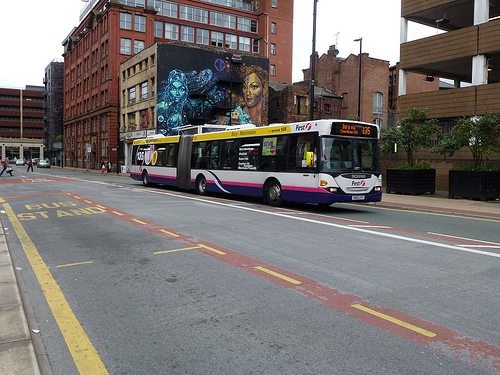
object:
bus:
[130, 118, 383, 209]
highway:
[1, 161, 499, 374]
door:
[358, 139, 374, 170]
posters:
[156, 43, 269, 133]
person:
[26, 157, 34, 172]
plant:
[381, 105, 446, 169]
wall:
[380, 155, 499, 199]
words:
[340, 123, 371, 135]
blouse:
[26, 161, 33, 166]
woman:
[223, 63, 269, 126]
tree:
[429, 109, 499, 171]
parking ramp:
[398, 0, 500, 159]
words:
[16, 200, 106, 221]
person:
[0, 154, 14, 177]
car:
[37, 160, 50, 169]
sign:
[85, 142, 91, 152]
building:
[0, 0, 294, 174]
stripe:
[190, 178, 332, 194]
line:
[14, 167, 499, 258]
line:
[0, 196, 109, 374]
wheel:
[195, 175, 207, 194]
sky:
[0, 0, 405, 90]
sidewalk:
[367, 196, 499, 221]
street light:
[353, 37, 363, 121]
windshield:
[320, 136, 379, 171]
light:
[330, 187, 337, 191]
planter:
[448, 169, 499, 202]